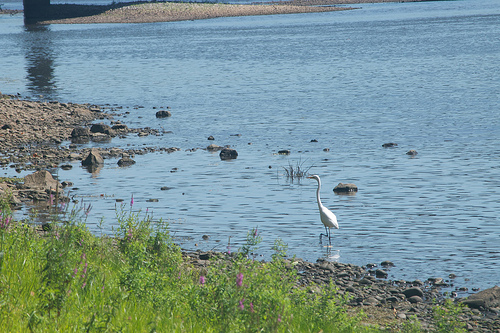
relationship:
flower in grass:
[202, 245, 256, 303] [51, 225, 211, 306]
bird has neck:
[283, 157, 358, 272] [308, 187, 334, 201]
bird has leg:
[283, 157, 358, 272] [304, 224, 378, 266]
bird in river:
[283, 157, 358, 272] [0, 0, 500, 289]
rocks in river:
[54, 91, 139, 164] [0, 0, 500, 289]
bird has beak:
[283, 157, 358, 272] [295, 168, 316, 189]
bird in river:
[299, 174, 340, 244] [0, 0, 500, 289]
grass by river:
[51, 225, 211, 306] [0, 0, 500, 289]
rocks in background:
[54, 91, 139, 164] [193, 4, 459, 77]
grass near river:
[51, 225, 211, 306] [0, 0, 500, 289]